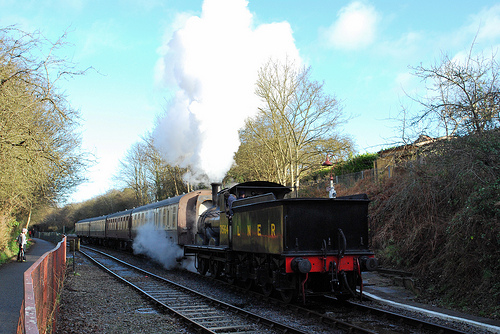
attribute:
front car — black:
[190, 171, 367, 297]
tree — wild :
[1, 25, 101, 257]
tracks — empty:
[74, 244, 303, 332]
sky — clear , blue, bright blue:
[2, 0, 498, 208]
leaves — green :
[24, 72, 106, 207]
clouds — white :
[348, 26, 445, 83]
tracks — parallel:
[74, 236, 272, 332]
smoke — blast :
[125, 213, 195, 275]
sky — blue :
[1, 37, 453, 178]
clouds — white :
[316, 12, 406, 50]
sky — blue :
[294, 28, 395, 108]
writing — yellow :
[215, 219, 280, 239]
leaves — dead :
[0, 23, 87, 230]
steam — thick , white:
[170, 16, 291, 195]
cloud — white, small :
[322, 0, 379, 62]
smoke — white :
[154, 5, 301, 195]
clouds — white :
[325, 11, 481, 108]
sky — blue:
[1, 6, 495, 191]